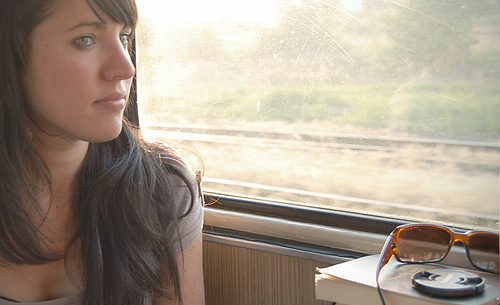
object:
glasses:
[371, 220, 500, 303]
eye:
[69, 30, 97, 49]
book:
[310, 248, 484, 303]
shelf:
[308, 294, 344, 303]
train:
[124, 0, 484, 302]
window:
[134, 0, 484, 236]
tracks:
[139, 116, 484, 232]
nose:
[100, 37, 138, 82]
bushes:
[202, 79, 280, 136]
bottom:
[199, 186, 398, 259]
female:
[1, 1, 205, 304]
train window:
[132, 0, 497, 231]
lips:
[94, 90, 129, 109]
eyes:
[120, 33, 131, 48]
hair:
[94, 164, 166, 286]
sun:
[139, 77, 200, 171]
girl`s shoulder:
[135, 135, 201, 188]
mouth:
[93, 88, 127, 108]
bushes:
[356, 83, 495, 135]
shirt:
[5, 153, 205, 301]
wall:
[202, 237, 335, 301]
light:
[396, 250, 443, 264]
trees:
[141, 3, 496, 85]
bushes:
[148, 84, 196, 117]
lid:
[410, 266, 484, 299]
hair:
[3, 0, 33, 240]